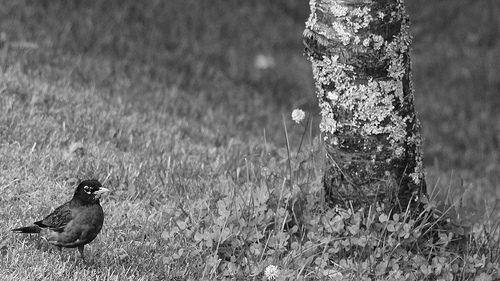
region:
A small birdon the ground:
[27, 170, 160, 248]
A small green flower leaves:
[223, 146, 288, 236]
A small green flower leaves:
[332, 202, 398, 268]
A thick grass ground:
[70, 75, 196, 172]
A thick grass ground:
[190, 26, 267, 117]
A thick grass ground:
[436, 74, 486, 202]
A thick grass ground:
[5, 41, 85, 146]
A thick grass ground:
[79, 22, 214, 106]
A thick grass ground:
[20, 249, 155, 278]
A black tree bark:
[310, 9, 420, 204]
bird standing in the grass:
[29, 162, 127, 257]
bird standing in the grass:
[57, 183, 119, 265]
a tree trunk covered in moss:
[298, 0, 446, 243]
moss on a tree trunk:
[298, 2, 435, 229]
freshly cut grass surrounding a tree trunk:
[1, 3, 498, 276]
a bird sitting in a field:
[16, 169, 112, 268]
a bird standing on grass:
[20, 175, 112, 262]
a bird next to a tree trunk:
[5, 172, 115, 264]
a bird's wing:
[12, 204, 77, 246]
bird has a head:
[70, 172, 113, 204]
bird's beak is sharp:
[93, 182, 113, 199]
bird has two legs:
[44, 235, 94, 267]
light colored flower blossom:
[290, 106, 306, 123]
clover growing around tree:
[172, 187, 496, 279]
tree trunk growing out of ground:
[301, 1, 428, 217]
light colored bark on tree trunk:
[307, 5, 416, 152]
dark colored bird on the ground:
[11, 173, 111, 263]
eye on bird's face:
[82, 183, 92, 195]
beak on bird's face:
[95, 183, 110, 195]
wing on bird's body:
[33, 206, 70, 230]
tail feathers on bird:
[12, 224, 37, 234]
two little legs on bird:
[54, 245, 91, 263]